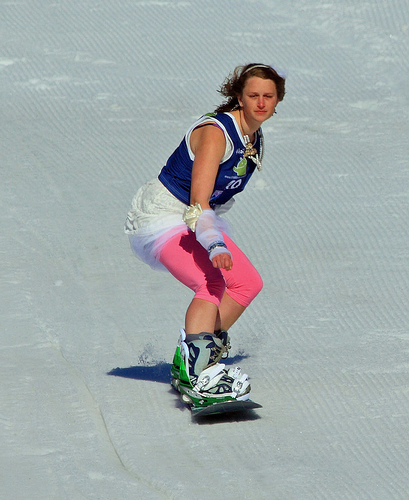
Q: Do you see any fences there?
A: No, there are no fences.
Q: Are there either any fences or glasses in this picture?
A: No, there are no fences or glasses.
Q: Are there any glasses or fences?
A: No, there are no fences or glasses.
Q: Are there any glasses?
A: No, there are no glasses.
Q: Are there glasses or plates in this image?
A: No, there are no glasses or plates.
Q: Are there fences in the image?
A: No, there are no fences.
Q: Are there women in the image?
A: Yes, there is a woman.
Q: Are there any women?
A: Yes, there is a woman.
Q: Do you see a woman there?
A: Yes, there is a woman.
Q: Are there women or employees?
A: Yes, there is a woman.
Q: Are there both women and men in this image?
A: No, there is a woman but no men.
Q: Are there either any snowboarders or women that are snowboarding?
A: Yes, the woman is snowboarding.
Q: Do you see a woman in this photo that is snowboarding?
A: Yes, there is a woman that is snowboarding.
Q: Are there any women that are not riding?
A: Yes, there is a woman that is snowboarding.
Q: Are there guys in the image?
A: No, there are no guys.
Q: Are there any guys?
A: No, there are no guys.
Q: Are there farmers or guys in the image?
A: No, there are no guys or farmers.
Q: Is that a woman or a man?
A: That is a woman.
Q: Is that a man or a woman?
A: That is a woman.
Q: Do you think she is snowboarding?
A: Yes, the woman is snowboarding.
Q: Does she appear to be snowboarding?
A: Yes, the woman is snowboarding.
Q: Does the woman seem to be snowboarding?
A: Yes, the woman is snowboarding.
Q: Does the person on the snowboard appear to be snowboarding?
A: Yes, the woman is snowboarding.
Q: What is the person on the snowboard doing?
A: The woman is snowboarding.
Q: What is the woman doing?
A: The woman is snowboarding.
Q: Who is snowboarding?
A: The woman is snowboarding.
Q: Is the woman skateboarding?
A: No, the woman is snowboarding.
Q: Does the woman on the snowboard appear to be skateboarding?
A: No, the woman is snowboarding.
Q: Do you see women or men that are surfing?
A: No, there is a woman but she is snowboarding.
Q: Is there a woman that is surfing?
A: No, there is a woman but she is snowboarding.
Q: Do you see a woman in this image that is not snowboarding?
A: No, there is a woman but she is snowboarding.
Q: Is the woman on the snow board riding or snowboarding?
A: The woman is snowboarding.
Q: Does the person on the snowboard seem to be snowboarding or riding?
A: The woman is snowboarding.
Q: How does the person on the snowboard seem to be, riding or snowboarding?
A: The woman is snowboarding.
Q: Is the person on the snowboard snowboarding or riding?
A: The woman is snowboarding.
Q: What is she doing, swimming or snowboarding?
A: The woman is snowboarding.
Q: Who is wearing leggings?
A: The woman is wearing leggings.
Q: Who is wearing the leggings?
A: The woman is wearing leggings.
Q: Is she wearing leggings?
A: Yes, the woman is wearing leggings.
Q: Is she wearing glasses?
A: No, the woman is wearing leggings.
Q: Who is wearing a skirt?
A: The woman is wearing a skirt.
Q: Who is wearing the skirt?
A: The woman is wearing a skirt.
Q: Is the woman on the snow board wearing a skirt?
A: Yes, the woman is wearing a skirt.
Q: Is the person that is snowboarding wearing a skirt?
A: Yes, the woman is wearing a skirt.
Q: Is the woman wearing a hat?
A: No, the woman is wearing a skirt.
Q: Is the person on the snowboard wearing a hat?
A: No, the woman is wearing a skirt.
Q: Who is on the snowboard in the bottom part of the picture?
A: The woman is on the snowboard.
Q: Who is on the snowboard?
A: The woman is on the snowboard.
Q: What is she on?
A: The woman is on the snowboard.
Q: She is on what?
A: The woman is on the snowboard.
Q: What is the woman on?
A: The woman is on the snowboard.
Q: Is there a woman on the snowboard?
A: Yes, there is a woman on the snowboard.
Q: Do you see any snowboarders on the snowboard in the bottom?
A: No, there is a woman on the snowboard.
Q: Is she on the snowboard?
A: Yes, the woman is on the snowboard.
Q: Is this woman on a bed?
A: No, the woman is on the snowboard.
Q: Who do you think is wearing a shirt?
A: The woman is wearing a shirt.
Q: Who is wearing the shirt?
A: The woman is wearing a shirt.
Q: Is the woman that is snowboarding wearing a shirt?
A: Yes, the woman is wearing a shirt.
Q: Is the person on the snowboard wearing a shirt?
A: Yes, the woman is wearing a shirt.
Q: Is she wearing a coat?
A: No, the woman is wearing a shirt.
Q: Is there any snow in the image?
A: Yes, there is snow.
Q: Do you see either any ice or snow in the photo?
A: Yes, there is snow.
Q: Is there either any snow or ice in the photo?
A: Yes, there is snow.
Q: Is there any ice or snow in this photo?
A: Yes, there is snow.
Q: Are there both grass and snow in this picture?
A: No, there is snow but no grass.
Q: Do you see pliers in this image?
A: No, there are no pliers.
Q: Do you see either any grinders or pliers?
A: No, there are no pliers or grinders.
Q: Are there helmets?
A: No, there are no helmets.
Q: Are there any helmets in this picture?
A: No, there are no helmets.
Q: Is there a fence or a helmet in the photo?
A: No, there are no helmets or fences.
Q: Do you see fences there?
A: No, there are no fences.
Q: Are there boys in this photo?
A: No, there are no boys.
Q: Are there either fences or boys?
A: No, there are no boys or fences.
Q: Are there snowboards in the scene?
A: Yes, there is a snowboard.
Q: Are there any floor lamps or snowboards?
A: Yes, there is a snowboard.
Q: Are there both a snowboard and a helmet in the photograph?
A: No, there is a snowboard but no helmets.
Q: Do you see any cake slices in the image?
A: No, there are no cake slices.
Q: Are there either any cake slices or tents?
A: No, there are no cake slices or tents.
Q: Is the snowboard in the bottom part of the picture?
A: Yes, the snowboard is in the bottom of the image.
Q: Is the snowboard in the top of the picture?
A: No, the snowboard is in the bottom of the image.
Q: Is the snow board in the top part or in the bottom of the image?
A: The snow board is in the bottom of the image.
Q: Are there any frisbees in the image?
A: No, there are no frisbees.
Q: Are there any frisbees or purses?
A: No, there are no frisbees or purses.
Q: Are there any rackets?
A: No, there are no rackets.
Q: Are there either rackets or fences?
A: No, there are no rackets or fences.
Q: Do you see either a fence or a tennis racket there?
A: No, there are no rackets or fences.